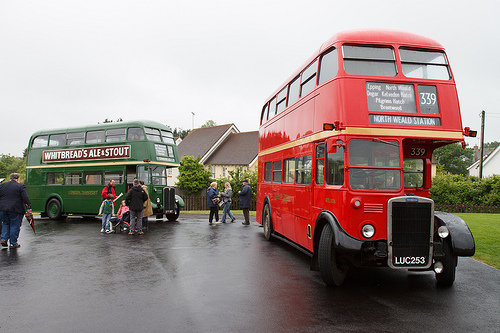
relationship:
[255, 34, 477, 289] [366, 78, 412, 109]
bus has sign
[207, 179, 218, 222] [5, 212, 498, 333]
woman standing on pavement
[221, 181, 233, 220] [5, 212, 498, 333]
woman standing in pavement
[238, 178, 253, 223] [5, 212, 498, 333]
man standing on pavement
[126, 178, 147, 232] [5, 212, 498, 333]
man standing on top of pavement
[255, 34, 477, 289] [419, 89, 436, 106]
bus says 339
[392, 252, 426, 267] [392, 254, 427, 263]
license plate reads luc253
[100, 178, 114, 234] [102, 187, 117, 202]
man wearing jacket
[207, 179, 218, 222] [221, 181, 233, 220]
woman ready to fight woman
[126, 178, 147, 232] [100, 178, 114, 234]
man standing by man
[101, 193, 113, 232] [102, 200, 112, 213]
child wearing vest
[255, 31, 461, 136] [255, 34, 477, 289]
upper deck of bus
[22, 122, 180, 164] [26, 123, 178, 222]
upper deck of bus